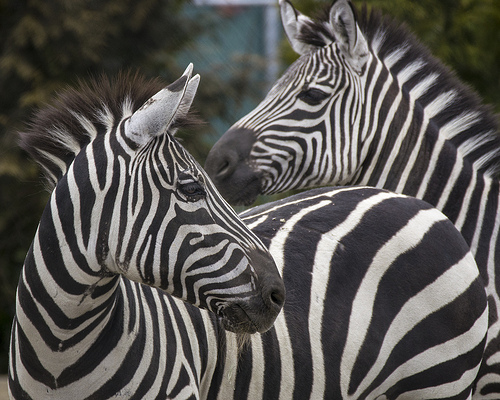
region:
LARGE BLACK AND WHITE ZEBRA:
[62, 91, 434, 393]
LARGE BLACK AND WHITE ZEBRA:
[216, 30, 486, 169]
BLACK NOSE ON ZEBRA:
[238, 250, 294, 346]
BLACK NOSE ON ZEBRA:
[197, 120, 237, 204]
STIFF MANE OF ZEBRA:
[47, 84, 131, 169]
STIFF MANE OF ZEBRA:
[412, 37, 493, 116]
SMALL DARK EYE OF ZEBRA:
[292, 67, 352, 109]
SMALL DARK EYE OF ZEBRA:
[171, 172, 206, 202]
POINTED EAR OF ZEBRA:
[110, 51, 215, 142]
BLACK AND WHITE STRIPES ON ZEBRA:
[277, 242, 490, 345]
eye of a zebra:
[170, 166, 210, 211]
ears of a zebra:
[110, 75, 205, 160]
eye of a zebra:
[291, 60, 331, 125]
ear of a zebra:
[330, 0, 360, 61]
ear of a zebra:
[275, 0, 306, 65]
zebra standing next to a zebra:
[30, 191, 485, 392]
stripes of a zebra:
[325, 205, 400, 316]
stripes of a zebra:
[382, 114, 432, 177]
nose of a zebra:
[255, 253, 286, 318]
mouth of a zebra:
[210, 297, 265, 355]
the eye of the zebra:
[180, 177, 200, 197]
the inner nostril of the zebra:
[265, 287, 280, 303]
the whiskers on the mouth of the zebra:
[212, 320, 252, 385]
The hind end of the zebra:
[300, 187, 452, 397]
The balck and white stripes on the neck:
[26, 146, 144, 398]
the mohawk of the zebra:
[14, 66, 203, 181]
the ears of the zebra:
[114, 56, 203, 149]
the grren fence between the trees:
[190, 0, 276, 127]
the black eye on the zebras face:
[297, 86, 330, 108]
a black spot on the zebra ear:
[165, 69, 188, 98]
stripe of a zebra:
[291, 275, 306, 292]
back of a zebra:
[403, 243, 421, 267]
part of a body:
[348, 199, 360, 214]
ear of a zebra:
[146, 113, 159, 134]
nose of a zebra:
[272, 274, 273, 318]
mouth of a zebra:
[228, 313, 240, 327]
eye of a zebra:
[314, 83, 329, 107]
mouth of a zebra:
[253, 308, 270, 332]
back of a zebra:
[437, 215, 452, 231]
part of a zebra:
[181, 263, 233, 298]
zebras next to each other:
[59, 0, 464, 362]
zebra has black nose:
[235, 260, 289, 343]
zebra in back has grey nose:
[202, 105, 246, 177]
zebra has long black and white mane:
[46, 55, 157, 180]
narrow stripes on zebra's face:
[160, 57, 277, 282]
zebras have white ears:
[127, 77, 205, 164]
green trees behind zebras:
[13, 1, 183, 141]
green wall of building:
[188, 18, 261, 145]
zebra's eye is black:
[162, 181, 212, 211]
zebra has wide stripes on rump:
[245, 226, 491, 389]